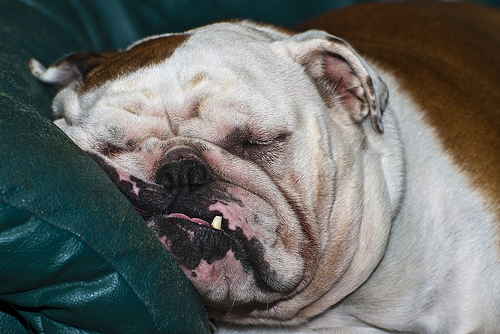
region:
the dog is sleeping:
[34, 41, 357, 310]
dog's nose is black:
[145, 137, 217, 227]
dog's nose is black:
[145, 111, 255, 241]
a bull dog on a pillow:
[17, 19, 489, 331]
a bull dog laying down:
[27, 20, 498, 328]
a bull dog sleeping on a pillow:
[15, 5, 485, 328]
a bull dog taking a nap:
[28, 18, 485, 331]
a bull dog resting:
[12, 12, 484, 330]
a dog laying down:
[18, 5, 492, 332]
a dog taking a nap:
[26, 12, 492, 327]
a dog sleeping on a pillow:
[10, 4, 499, 319]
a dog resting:
[20, 2, 490, 330]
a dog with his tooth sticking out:
[207, 207, 233, 241]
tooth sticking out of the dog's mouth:
[207, 209, 227, 237]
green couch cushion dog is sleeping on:
[6, 131, 148, 320]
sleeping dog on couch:
[31, 33, 430, 325]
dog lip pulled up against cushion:
[67, 128, 169, 222]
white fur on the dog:
[417, 188, 464, 290]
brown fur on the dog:
[425, 20, 468, 91]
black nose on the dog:
[145, 154, 218, 196]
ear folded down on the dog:
[283, 19, 395, 151]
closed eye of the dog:
[224, 123, 299, 163]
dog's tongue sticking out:
[169, 205, 213, 230]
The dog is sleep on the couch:
[39, 43, 453, 307]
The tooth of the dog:
[202, 205, 227, 235]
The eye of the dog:
[220, 111, 297, 161]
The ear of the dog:
[289, 22, 399, 132]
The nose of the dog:
[155, 152, 211, 193]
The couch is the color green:
[13, 175, 125, 304]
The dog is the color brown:
[374, 0, 494, 69]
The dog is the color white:
[388, 208, 497, 313]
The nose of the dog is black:
[154, 153, 224, 207]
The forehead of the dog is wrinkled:
[108, 68, 229, 147]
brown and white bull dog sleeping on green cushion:
[27, 0, 492, 330]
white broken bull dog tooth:
[204, 208, 225, 234]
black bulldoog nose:
[155, 158, 211, 193]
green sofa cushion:
[2, 2, 214, 328]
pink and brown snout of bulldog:
[90, 150, 277, 307]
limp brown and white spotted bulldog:
[275, 18, 406, 145]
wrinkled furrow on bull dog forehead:
[105, 70, 225, 136]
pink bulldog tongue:
[164, 208, 213, 230]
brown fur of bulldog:
[407, 68, 492, 102]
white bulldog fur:
[410, 238, 480, 298]